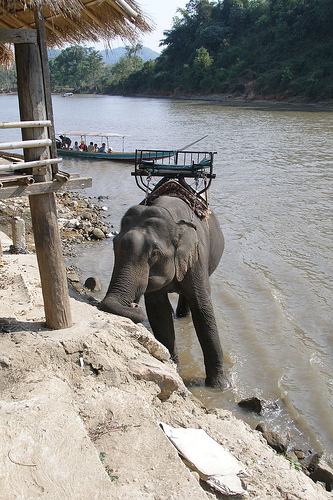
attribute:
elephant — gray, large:
[103, 201, 235, 370]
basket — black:
[135, 151, 227, 190]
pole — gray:
[28, 215, 71, 302]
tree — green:
[251, 21, 273, 49]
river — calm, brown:
[246, 129, 284, 170]